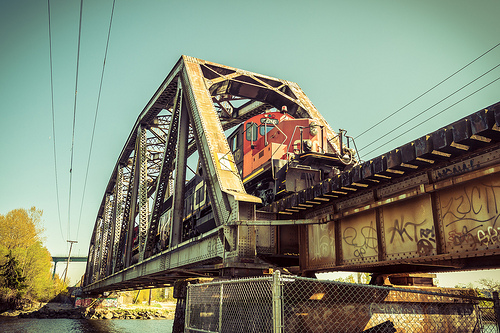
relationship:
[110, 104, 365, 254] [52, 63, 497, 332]
train on a bridge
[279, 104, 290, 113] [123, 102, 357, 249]
light on top of a train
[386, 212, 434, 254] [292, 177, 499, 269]
graffiti on metal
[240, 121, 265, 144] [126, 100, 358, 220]
window on a train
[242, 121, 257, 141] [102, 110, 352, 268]
windshield of train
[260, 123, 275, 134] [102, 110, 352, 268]
windshield of train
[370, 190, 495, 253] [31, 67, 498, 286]
graffiti on bridge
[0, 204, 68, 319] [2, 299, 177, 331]
tree next to water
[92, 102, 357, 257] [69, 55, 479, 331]
train on bridge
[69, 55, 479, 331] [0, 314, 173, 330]
bridge over water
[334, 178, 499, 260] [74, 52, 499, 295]
graffiti on bridge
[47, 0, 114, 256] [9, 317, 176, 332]
electrical lines over water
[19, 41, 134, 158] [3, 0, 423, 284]
cloud in sky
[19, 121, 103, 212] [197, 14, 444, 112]
cloud in sky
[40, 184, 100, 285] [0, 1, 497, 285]
cloud in sky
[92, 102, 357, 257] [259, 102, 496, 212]
train on track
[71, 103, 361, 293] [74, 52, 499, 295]
train on bridge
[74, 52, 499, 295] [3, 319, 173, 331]
bridge across water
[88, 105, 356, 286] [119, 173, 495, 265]
train moving on bridge